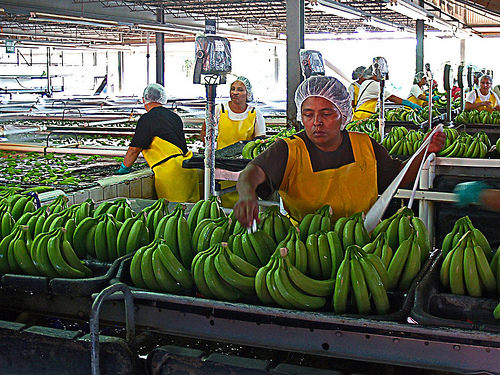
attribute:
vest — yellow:
[216, 108, 255, 148]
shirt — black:
[129, 110, 187, 155]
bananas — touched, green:
[231, 223, 276, 270]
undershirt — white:
[215, 104, 266, 139]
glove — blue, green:
[118, 163, 135, 174]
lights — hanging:
[306, 1, 417, 41]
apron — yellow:
[142, 137, 199, 205]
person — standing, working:
[118, 83, 204, 206]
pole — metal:
[203, 85, 217, 200]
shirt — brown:
[246, 132, 400, 200]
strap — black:
[150, 153, 188, 169]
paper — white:
[359, 120, 444, 231]